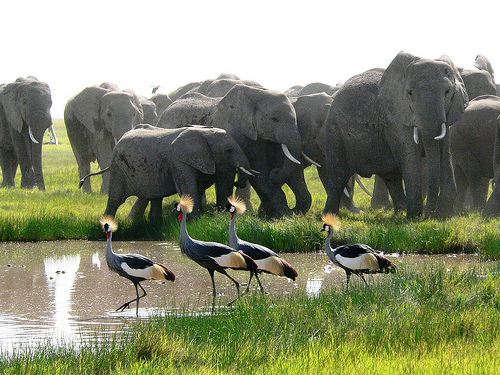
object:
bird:
[222, 195, 298, 308]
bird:
[318, 210, 397, 295]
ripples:
[1, 313, 135, 349]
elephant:
[271, 91, 337, 218]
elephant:
[1, 75, 60, 191]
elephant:
[63, 82, 157, 194]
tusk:
[280, 142, 301, 165]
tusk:
[301, 150, 321, 167]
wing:
[197, 242, 248, 268]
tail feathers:
[374, 256, 400, 275]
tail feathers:
[280, 264, 299, 281]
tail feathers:
[237, 252, 258, 273]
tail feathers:
[163, 269, 176, 282]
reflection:
[303, 273, 328, 298]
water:
[0, 237, 497, 363]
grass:
[319, 294, 447, 365]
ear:
[169, 127, 216, 175]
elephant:
[447, 91, 498, 221]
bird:
[99, 215, 177, 318]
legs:
[220, 270, 241, 305]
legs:
[210, 272, 216, 315]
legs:
[226, 272, 254, 307]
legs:
[345, 272, 352, 292]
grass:
[5, 339, 184, 370]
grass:
[158, 323, 248, 373]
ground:
[0, 264, 499, 370]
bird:
[170, 194, 260, 316]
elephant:
[79, 122, 261, 225]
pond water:
[4, 247, 104, 345]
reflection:
[38, 249, 85, 348]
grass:
[49, 205, 474, 248]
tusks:
[343, 187, 349, 198]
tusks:
[352, 173, 373, 197]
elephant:
[157, 84, 324, 222]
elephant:
[322, 50, 469, 219]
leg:
[133, 284, 138, 318]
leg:
[114, 281, 148, 312]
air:
[12, 10, 62, 64]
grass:
[286, 267, 500, 326]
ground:
[0, 118, 499, 254]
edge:
[207, 250, 232, 258]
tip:
[293, 160, 301, 165]